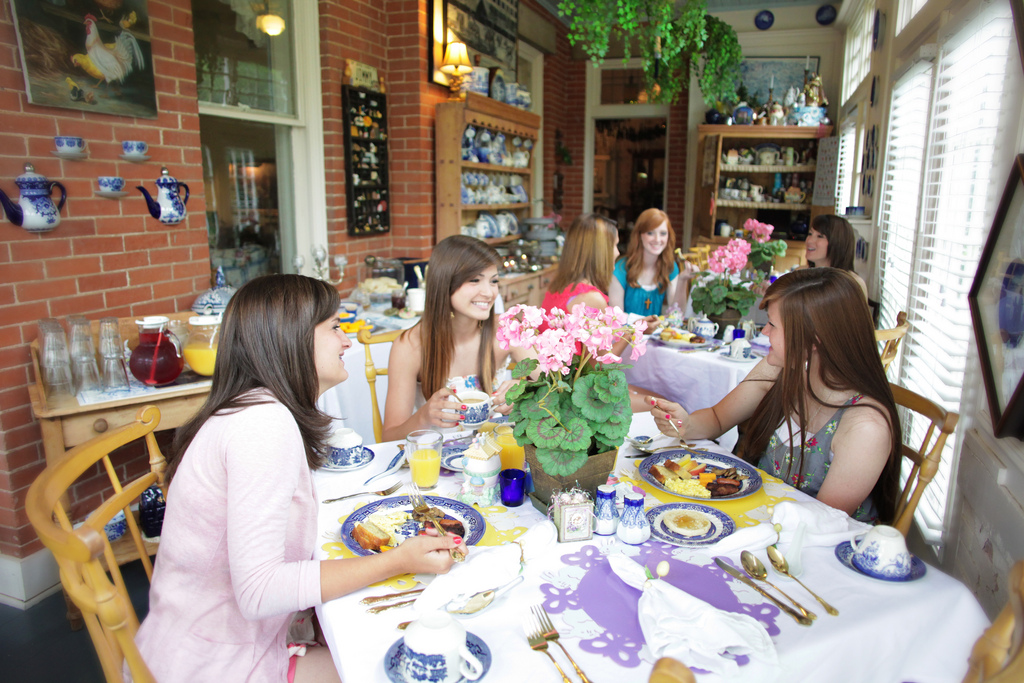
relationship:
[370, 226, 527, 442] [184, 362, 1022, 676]
girl at table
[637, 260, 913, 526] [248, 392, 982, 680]
girl at table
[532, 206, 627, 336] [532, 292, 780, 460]
girl at table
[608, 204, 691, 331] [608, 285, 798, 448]
girl at table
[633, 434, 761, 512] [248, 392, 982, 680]
plate on table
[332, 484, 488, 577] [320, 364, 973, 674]
plate on table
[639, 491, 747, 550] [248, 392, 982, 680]
plate on table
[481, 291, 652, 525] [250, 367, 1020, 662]
plant on table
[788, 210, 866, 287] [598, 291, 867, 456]
girl sitting down at table